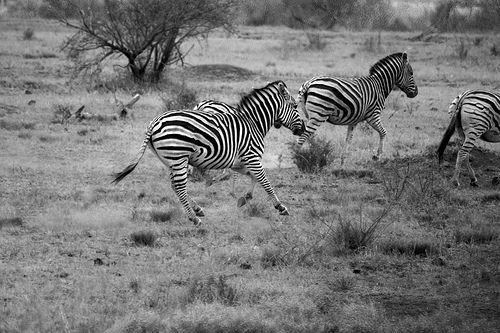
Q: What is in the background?
A: Trees and grasses.